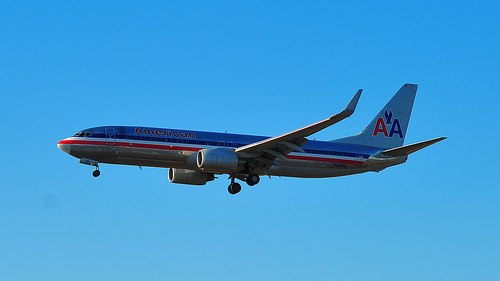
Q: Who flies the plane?
A: The pilot.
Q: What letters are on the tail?
A: AA.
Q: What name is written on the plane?
A: American.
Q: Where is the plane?
A: In the sky.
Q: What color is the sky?
A: Blue.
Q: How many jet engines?
A: 2.